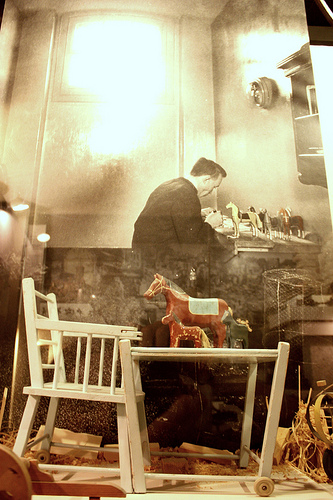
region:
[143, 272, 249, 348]
Three wooden horses on a desk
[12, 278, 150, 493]
white wooden chair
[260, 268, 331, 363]
chicken wire basket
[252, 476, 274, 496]
round wooden desk wheel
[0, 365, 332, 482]
hay on the floor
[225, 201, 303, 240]
wooden horses on desktop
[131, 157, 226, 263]
man in black jacket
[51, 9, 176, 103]
light through the window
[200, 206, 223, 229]
mans hands carving wood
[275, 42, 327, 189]
hanging shelves on wall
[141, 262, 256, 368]
Wooden horses on a table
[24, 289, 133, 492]
A white chair made of wood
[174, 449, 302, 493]
The table has a wheel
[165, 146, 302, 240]
The man is painting wooden horses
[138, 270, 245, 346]
Two wooden horses painted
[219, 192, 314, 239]
Many wooden horses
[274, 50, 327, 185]
A shelf on the wall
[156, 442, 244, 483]
wood shavings on the floor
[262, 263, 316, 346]
Chicken wire in a circle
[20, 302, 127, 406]
The chair is painted white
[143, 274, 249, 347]
a horse wood carving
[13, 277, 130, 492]
a natural wood chair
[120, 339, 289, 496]
a natural wood tray table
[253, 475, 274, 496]
the wheels on the table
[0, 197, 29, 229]
a light source reflecting on the store window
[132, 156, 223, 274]
a man working on a carving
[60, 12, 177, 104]
bright sunlight shinning through the window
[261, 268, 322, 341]
a reflection of a metal basket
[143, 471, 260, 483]
horizontal support pieces on the table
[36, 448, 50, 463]
a wheel on the chair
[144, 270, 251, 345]
Three wooden toy horses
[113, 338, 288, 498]
White children's table with wheels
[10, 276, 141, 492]
Child sized white wooden chair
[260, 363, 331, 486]
Wood shavings strewn on floor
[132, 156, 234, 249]
Wood worker bent over toy wooden horses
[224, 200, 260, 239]
White wooden toy horse wearing a saddle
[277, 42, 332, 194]
Two shelf book case attached to wall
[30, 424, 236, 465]
Wooden blocks tossed on the floor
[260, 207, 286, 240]
Grey toy wooden horse with white socks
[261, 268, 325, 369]
Metal net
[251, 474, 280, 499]
a tan wheel on the desk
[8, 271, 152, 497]
a white highchair made of wood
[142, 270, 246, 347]
two wooden horse statues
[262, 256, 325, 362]
small circular basket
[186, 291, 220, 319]
white saddle painted on a horse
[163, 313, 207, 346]
baby horse on the table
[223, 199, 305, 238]
many horse statues on the shelf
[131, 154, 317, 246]
man sitting in a shop making horses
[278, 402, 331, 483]
fake horse hay on the ground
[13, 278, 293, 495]
white wooden furniture set